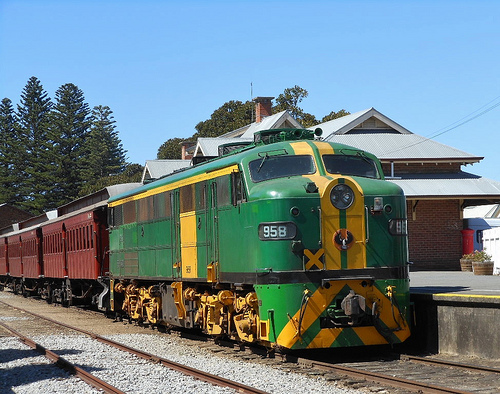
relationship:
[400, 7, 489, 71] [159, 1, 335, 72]
blue clear sky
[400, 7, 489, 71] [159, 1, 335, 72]
blue cloudless sky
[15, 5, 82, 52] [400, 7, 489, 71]
cloudless sky blue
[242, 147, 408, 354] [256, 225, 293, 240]
train has numbers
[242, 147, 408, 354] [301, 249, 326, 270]
train has x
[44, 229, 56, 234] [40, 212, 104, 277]
red box cars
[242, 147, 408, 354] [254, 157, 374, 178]
train has windows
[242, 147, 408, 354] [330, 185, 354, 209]
train has light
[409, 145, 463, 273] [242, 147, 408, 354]
station behind train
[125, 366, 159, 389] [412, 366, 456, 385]
gravel between tracks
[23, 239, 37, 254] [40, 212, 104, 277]
windows on cars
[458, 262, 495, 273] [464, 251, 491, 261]
pots with flowers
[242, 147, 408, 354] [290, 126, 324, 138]
train has horns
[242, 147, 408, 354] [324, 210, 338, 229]
train has yellow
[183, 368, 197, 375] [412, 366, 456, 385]
metal on tracks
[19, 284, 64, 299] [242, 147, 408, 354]
wheels on train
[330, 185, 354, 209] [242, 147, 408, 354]
headlight on train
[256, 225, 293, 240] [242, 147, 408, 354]
number on train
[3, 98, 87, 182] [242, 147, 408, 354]
trees behind train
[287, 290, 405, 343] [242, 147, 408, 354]
stripes on train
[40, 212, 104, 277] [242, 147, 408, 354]
cars behind train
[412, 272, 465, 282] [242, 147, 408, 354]
concrete near train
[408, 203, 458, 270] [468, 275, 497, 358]
building near platform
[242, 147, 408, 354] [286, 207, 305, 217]
train has headlight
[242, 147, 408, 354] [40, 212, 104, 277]
train attached to cars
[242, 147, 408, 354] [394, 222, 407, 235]
train has number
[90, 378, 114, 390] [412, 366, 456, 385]
steel railroad tracks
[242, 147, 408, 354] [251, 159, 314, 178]
train has windshield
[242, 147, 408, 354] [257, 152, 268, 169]
train has wiper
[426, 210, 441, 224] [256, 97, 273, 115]
red brick chimney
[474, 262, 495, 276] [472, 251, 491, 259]
pot with plant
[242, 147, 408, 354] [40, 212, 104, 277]
train passenger cars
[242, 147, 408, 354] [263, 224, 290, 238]
train say 958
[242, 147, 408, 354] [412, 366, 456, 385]
train on tracks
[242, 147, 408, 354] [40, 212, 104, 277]
train has cars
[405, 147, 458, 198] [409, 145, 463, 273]
roof on station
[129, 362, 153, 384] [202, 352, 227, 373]
stones on ground